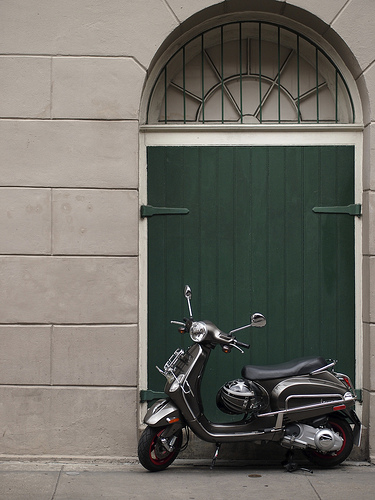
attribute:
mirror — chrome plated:
[245, 308, 270, 329]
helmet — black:
[214, 373, 265, 414]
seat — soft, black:
[244, 354, 330, 380]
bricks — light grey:
[4, 189, 132, 322]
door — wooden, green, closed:
[147, 145, 355, 429]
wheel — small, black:
[122, 400, 197, 473]